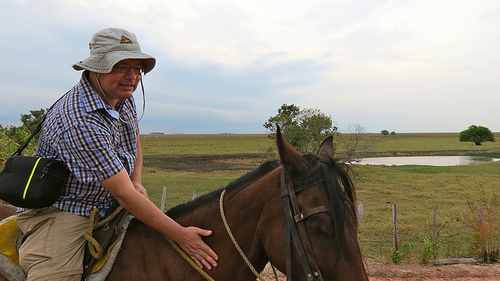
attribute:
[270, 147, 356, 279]
harness — leather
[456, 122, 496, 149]
tree — leafy, green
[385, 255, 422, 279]
dirt — black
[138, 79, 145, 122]
strap — hat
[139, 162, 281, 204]
mane — black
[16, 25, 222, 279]
man — older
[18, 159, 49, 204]
stripe — yellow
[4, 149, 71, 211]
bag — black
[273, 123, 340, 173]
ears — long, brown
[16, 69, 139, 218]
plaid shirt — blue, yellow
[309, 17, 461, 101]
clouds — thick, white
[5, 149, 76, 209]
bag — black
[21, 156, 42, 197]
stripe — yellow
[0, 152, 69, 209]
bag — black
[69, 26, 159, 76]
hat — floppy, khaki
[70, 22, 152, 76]
hat — tan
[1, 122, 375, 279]
horse — brown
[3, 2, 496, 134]
sky — cloudy, blue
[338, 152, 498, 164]
lake — calm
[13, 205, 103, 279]
cargo pants — khaki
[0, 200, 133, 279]
saddle — brown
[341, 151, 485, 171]
body — water